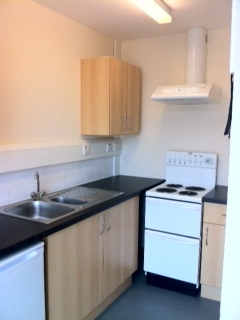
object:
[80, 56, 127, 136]
cabinets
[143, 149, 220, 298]
stove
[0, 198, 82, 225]
sink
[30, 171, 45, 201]
faucet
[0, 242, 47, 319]
dishwasher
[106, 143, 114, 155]
electrical outlet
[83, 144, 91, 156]
electrical outlet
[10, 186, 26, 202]
tile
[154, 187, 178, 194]
electric burner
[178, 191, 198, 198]
electric burner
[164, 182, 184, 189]
electric burner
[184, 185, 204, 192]
electric burner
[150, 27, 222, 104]
electric vent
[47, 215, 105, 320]
cabinets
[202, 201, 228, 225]
drawer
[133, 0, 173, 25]
light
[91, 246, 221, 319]
floor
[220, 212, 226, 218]
drawer pull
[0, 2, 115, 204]
wall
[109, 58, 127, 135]
door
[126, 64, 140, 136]
door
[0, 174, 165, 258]
counter top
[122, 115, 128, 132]
handle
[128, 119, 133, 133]
handle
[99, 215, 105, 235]
handles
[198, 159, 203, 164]
panel of buttons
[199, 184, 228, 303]
cabinet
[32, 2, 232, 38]
ceiling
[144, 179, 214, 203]
stove top